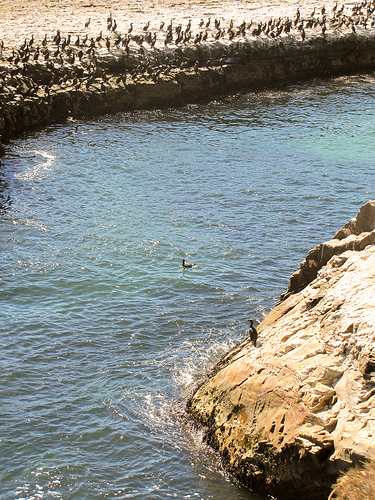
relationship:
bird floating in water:
[182, 254, 195, 267] [1, 72, 373, 498]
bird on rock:
[247, 319, 258, 347] [186, 199, 374, 499]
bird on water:
[182, 254, 195, 267] [1, 72, 373, 498]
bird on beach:
[39, 28, 52, 47] [4, 7, 154, 82]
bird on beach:
[201, 14, 213, 28] [2, 2, 374, 82]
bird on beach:
[139, 15, 149, 31] [7, 2, 373, 68]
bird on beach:
[164, 15, 177, 32] [74, 7, 289, 73]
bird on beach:
[123, 17, 133, 31] [2, 2, 374, 82]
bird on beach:
[39, 26, 51, 46] [4, 5, 205, 92]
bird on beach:
[148, 30, 161, 44] [22, 6, 263, 86]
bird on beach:
[161, 24, 175, 48] [71, 9, 276, 79]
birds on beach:
[10, 2, 374, 64] [2, 2, 374, 82]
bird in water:
[179, 253, 193, 269] [145, 219, 236, 306]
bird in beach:
[84, 18, 91, 29] [52, 5, 137, 52]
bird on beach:
[142, 21, 151, 33] [7, 5, 334, 67]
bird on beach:
[142, 21, 151, 33] [14, 7, 309, 79]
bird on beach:
[224, 17, 237, 29] [164, 6, 283, 60]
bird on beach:
[125, 22, 134, 35] [67, 5, 227, 73]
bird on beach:
[172, 32, 185, 44] [52, 13, 260, 72]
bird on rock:
[247, 319, 258, 347] [232, 349, 343, 405]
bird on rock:
[243, 308, 260, 343] [279, 373, 337, 430]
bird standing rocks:
[247, 319, 258, 347] [217, 374, 352, 444]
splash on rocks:
[177, 338, 230, 397] [195, 381, 298, 400]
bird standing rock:
[247, 319, 258, 347] [217, 357, 320, 414]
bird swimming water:
[182, 254, 195, 267] [56, 284, 180, 365]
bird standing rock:
[247, 319, 258, 347] [230, 346, 305, 369]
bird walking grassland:
[5, 24, 253, 75] [9, 14, 188, 44]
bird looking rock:
[247, 319, 258, 347] [240, 344, 349, 398]